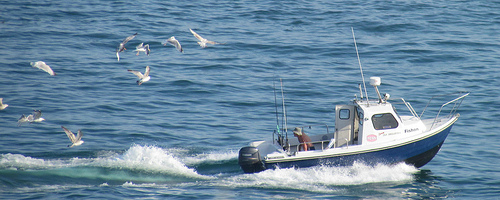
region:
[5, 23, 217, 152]
flock of sea birds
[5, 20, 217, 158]
flock of sea gulls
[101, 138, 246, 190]
wake created by boat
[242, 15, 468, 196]
a small blue and white fishing boat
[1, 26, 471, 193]
flock of birds chasing a fishing boat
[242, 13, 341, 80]
water of the ocean is relatively calm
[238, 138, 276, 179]
out board motor of small boat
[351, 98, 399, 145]
cabin of a small fishing boat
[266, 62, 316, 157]
a man with fishing poles on back of boat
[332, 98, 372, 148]
door to boat cabin is open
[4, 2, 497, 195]
surface of rough water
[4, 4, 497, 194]
surface of blue water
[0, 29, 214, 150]
flying seagulls over water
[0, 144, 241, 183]
wake made by boat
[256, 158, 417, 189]
white water splashes beside boat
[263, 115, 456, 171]
body of blue and black boat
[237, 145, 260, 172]
engine on back of boat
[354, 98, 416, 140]
wheel house on boat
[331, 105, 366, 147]
open door of wheel house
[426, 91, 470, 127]
railing on bow of boat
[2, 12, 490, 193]
A boat is traveling on the water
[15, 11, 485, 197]
A boat is moving very fast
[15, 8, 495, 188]
A person has just gone fishing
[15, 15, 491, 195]
A person is trying to catch fish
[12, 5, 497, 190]
Some birds are following a boat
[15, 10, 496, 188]
Some birds are searching for food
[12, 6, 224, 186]
Some birds are flying over the water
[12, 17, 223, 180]
The birds are male and female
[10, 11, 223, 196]
The birds are out in the sunshine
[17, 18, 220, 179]
The birds are enjoying the day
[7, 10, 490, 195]
A boat is going out fishing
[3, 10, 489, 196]
A boat is leaving a big wake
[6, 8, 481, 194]
A person is doing some boating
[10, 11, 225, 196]
Some birds are looking for food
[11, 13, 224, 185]
The birds are hunting for a meal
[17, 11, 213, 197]
The birds are flying around quickly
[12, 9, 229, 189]
The birds are having a great day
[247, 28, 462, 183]
This boat is fast.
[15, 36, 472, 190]
It is leaving a wake.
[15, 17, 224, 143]
The birds are white.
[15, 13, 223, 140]
The birds are flying.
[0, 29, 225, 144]
The birds are following teh boat.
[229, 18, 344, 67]
The water is blue.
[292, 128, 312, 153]
The man's shirt is brown.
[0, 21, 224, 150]
There are nine birds.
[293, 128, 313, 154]
The man is wearing a hat.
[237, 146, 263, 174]
There is an engine.